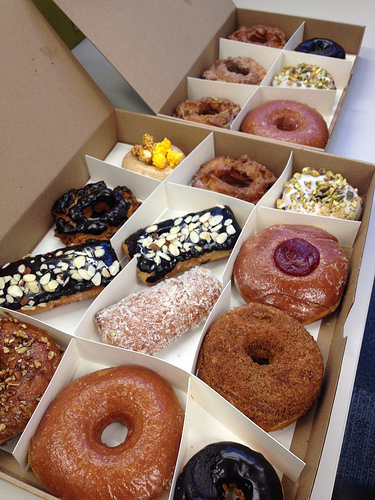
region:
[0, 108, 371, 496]
Box with white partitions containing various donuts and other sweets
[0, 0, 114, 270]
Brown cover of the box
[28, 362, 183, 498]
A glazed donut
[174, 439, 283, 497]
Donut with chocolate icing on top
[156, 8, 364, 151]
Another smaller box of donuts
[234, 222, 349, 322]
Glazed donut with starwberry jam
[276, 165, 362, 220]
Donut with white icing and dry fruit pieces on top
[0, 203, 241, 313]
Rectangular aweets with chocolate icing and nut flakes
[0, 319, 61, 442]
Donut with honey and walnut topping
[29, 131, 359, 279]
White partition plates kept in the box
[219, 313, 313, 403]
the donut is brown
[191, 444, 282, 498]
chocltae topping is on the donut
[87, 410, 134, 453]
hole is in the donut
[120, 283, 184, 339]
white topping is on the donut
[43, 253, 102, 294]
nuts are on the cake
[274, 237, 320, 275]
puerple topping is on the donut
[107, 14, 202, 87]
the cardboard is brown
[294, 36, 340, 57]
the donut is black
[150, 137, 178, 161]
yellow topings are on the donut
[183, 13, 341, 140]
six donuts are in the box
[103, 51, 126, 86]
edge of a knife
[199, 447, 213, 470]
aprt of a cream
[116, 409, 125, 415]
edge of a hle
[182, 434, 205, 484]
edge of a box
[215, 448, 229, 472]
part fo a crea,m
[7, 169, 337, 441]
box of different donuts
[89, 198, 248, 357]
two different donuts in box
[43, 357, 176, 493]
glazed donut in box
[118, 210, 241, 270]
nut covered donut with chocolate frosting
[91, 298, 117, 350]
part of a powdered donut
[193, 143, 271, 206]
sour cream donut in box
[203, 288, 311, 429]
cinnamon covered plain donut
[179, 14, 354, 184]
donuts in a box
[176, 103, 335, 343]
donuts in a box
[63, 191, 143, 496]
donuts in a box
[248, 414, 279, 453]
edge of a bx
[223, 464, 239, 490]
part of a cream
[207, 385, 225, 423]
edge of a box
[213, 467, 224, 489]
aprt of a cream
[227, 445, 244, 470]
part f a cream